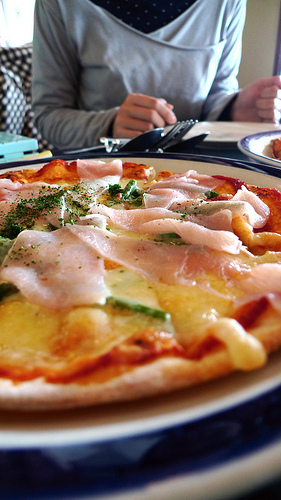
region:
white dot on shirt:
[144, 21, 150, 25]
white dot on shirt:
[162, 21, 166, 24]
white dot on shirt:
[127, 22, 133, 26]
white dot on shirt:
[125, 11, 130, 16]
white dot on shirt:
[135, 16, 139, 20]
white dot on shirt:
[143, 9, 147, 13]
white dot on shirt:
[160, 9, 164, 14]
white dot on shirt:
[105, 0, 110, 5]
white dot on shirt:
[167, 2, 172, 6]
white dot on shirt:
[183, 1, 189, 6]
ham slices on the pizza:
[1, 224, 107, 308]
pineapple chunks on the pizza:
[154, 281, 234, 336]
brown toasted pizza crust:
[5, 159, 77, 183]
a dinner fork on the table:
[163, 119, 198, 147]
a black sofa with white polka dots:
[0, 46, 33, 133]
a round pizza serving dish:
[154, 149, 280, 173]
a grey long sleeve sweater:
[33, 0, 246, 93]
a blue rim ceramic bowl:
[237, 128, 279, 168]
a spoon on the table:
[178, 131, 210, 151]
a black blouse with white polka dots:
[137, 0, 161, 28]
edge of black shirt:
[123, 8, 169, 30]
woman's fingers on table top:
[129, 91, 173, 125]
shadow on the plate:
[125, 388, 166, 410]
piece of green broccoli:
[111, 182, 157, 202]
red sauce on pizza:
[86, 351, 137, 371]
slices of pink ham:
[52, 226, 233, 287]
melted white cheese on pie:
[105, 275, 201, 319]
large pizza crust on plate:
[33, 154, 261, 382]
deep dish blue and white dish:
[235, 134, 268, 154]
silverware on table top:
[132, 117, 212, 146]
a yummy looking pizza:
[1, 158, 280, 496]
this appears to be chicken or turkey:
[12, 221, 166, 318]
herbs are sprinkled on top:
[3, 175, 150, 225]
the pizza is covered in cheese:
[26, 307, 220, 359]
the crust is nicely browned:
[37, 160, 271, 225]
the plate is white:
[37, 405, 277, 430]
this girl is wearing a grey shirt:
[39, 7, 244, 138]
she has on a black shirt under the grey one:
[110, 6, 185, 25]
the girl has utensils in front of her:
[100, 120, 216, 156]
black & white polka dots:
[4, 43, 34, 145]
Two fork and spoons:
[83, 112, 215, 160]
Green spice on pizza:
[3, 164, 239, 322]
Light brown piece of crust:
[1, 150, 280, 414]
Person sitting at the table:
[22, 1, 280, 160]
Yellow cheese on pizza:
[5, 186, 280, 387]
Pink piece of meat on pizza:
[0, 159, 279, 310]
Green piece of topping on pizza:
[88, 287, 188, 337]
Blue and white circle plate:
[0, 146, 279, 457]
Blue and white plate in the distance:
[233, 111, 279, 172]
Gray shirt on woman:
[23, 0, 270, 146]